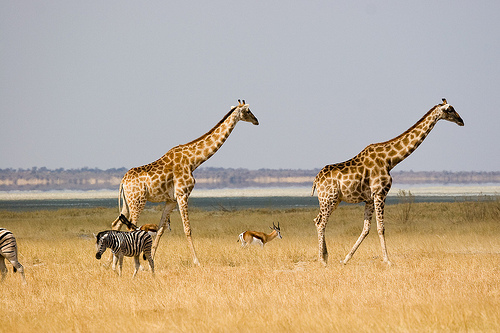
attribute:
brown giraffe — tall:
[106, 99, 261, 271]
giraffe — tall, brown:
[309, 91, 464, 269]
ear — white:
[240, 102, 249, 109]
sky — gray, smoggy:
[2, 7, 489, 180]